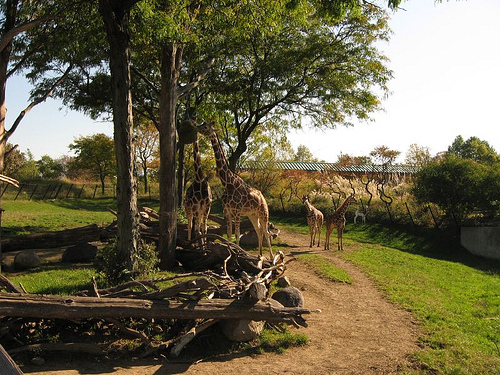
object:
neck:
[211, 134, 233, 185]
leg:
[247, 213, 274, 257]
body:
[196, 121, 274, 260]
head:
[197, 121, 217, 136]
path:
[21, 223, 419, 375]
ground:
[1, 216, 500, 375]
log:
[176, 242, 279, 279]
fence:
[261, 163, 462, 230]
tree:
[0, 0, 406, 285]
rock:
[222, 319, 264, 341]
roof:
[237, 162, 443, 173]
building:
[236, 161, 421, 189]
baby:
[302, 194, 324, 248]